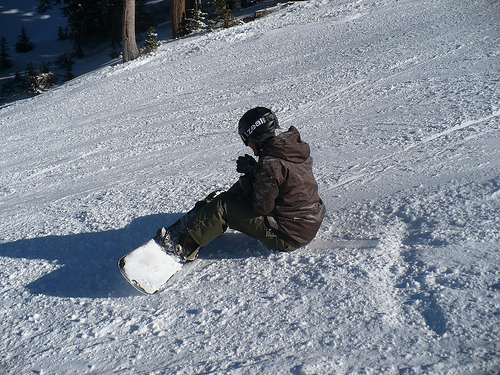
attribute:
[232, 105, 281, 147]
helmet — black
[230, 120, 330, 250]
coat — brown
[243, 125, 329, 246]
jacket — brown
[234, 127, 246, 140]
goggles — black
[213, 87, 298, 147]
helmet — black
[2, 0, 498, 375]
snow — white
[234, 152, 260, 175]
glove — black, padded , winter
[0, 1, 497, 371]
slope — snowy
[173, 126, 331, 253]
snow suit — brown, padded